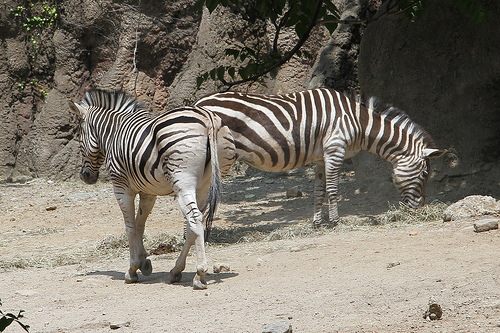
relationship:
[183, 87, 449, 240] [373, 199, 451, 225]
zebra grazing on grass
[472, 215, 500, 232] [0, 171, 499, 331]
rock on ground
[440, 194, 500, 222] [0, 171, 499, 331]
rock on ground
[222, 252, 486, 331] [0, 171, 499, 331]
dirt on ground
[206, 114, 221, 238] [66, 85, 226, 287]
tail on zebra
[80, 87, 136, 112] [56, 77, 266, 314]
mane on zebra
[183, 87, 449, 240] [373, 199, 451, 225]
zebra eating grass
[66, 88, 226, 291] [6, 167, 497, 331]
zebra on dirt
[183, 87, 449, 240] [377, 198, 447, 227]
zebra eating grass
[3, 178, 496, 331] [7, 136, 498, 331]
sand on ground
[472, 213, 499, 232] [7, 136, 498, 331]
rock on ground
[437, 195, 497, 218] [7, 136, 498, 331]
rock on ground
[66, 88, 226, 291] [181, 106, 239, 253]
zebra has tail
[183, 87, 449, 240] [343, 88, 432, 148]
zebra has mane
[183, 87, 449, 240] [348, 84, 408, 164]
zebra has neck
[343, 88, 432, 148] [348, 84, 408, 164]
mane on neck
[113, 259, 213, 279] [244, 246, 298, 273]
shadow on ground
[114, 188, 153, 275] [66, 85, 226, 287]
leg on zebra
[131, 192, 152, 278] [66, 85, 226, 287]
leg on zebra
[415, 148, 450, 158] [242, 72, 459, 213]
ear on zebra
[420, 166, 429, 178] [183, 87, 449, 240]
eye on zebra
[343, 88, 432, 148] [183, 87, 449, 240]
mane of zebra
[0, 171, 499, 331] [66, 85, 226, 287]
ground beneath zebra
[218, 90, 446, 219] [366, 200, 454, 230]
zebra eating grass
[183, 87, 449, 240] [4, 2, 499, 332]
zebra in an enclosure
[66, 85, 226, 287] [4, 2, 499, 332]
zebra in an enclosure